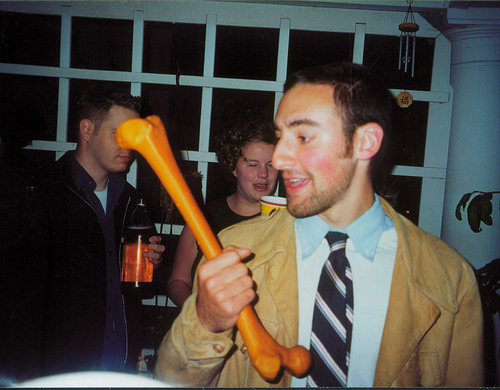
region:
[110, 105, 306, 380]
very large orange bone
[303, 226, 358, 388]
black neck tie with diagonal silver and blue stripes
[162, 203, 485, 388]
gold leather jacket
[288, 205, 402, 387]
light blue dress shirt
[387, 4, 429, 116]
small set of windchimes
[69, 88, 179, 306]
man drinks from large bottle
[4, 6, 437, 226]
white grid wall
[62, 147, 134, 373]
purple shirt buttoned over a white t-shirt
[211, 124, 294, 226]
lady drinks from white and yellow cup with red stripe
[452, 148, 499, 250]
a limp branch of a plant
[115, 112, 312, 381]
a large orange bone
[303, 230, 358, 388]
man wearing a striped necktie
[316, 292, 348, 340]
stripe on tie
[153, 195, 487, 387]
man wearing a tan jacket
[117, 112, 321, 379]
bone in fist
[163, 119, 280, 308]
woman standing behind man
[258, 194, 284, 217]
yellow cup behind man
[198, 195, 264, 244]
woman wearing a black sleeveless shirt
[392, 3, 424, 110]
wind chime hanging behind man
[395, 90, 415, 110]
disc hanging on wind chime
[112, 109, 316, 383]
a golden femur bone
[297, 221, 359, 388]
a navy blue tie with pink stripes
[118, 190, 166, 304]
A forty ounce bottle of malt liquor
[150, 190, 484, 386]
a tan trenchcoat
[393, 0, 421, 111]
a wood and metal windchime with Asian writing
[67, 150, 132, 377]
a dark purple button down shirt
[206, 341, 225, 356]
the brown button of a tan trenchcoat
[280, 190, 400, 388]
a light blue button down dress shirt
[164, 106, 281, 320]
a woman wearing a black shirt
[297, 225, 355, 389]
a blue and pink tie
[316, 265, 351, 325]
navy blue diagonal stripe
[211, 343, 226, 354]
brown button on sleeve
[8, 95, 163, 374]
man holding a large bottle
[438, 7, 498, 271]
white column next to wind chime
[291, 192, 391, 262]
blue collar on shirt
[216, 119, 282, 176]
woman with curly hair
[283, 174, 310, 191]
man with open mouth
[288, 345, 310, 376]
knob on end of bone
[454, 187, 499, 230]
leaf next to column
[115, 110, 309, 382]
long, orange bone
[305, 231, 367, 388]
blue striped tie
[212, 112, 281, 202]
woman with short, curly hair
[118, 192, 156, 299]
large bottle of amber colored liquid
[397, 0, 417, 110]
wind chime hanging in the window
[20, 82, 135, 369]
man in a black jacket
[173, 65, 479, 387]
man in a tan jacket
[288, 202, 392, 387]
light blue button up shirt with a dark blue tie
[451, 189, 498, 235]
green leaves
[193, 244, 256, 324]
hand holding a bone